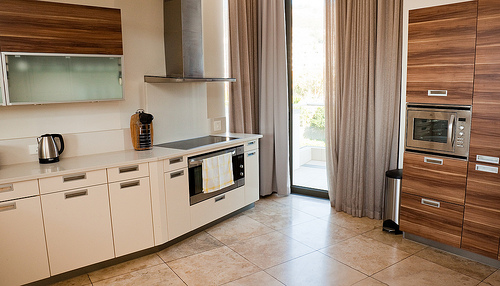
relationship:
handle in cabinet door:
[418, 199, 442, 210] [394, 182, 461, 247]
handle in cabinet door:
[479, 158, 498, 180] [465, 16, 497, 271]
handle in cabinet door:
[478, 154, 494, 169] [469, 108, 498, 228]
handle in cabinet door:
[63, 189, 88, 199] [49, 177, 123, 274]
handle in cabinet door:
[0, 203, 22, 207] [10, 188, 38, 281]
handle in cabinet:
[64, 169, 90, 185] [39, 182, 117, 278]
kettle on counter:
[34, 130, 68, 169] [1, 162, 180, 181]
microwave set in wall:
[404, 102, 471, 157] [388, 2, 498, 242]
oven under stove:
[189, 148, 258, 198] [154, 129, 238, 151]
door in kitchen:
[289, 0, 328, 197] [10, 7, 487, 277]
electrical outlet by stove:
[201, 115, 230, 139] [156, 140, 261, 217]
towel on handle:
[200, 152, 237, 194] [173, 149, 251, 178]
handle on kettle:
[46, 127, 73, 157] [39, 125, 77, 168]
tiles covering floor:
[177, 239, 307, 279] [258, 232, 309, 253]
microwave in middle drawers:
[397, 98, 480, 157] [401, 38, 458, 236]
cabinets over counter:
[7, 34, 115, 103] [16, 156, 123, 200]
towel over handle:
[195, 145, 264, 205] [188, 151, 257, 179]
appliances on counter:
[21, 124, 179, 164] [25, 163, 110, 173]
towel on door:
[200, 152, 237, 194] [185, 143, 244, 206]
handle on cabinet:
[476, 164, 499, 173] [462, 105, 497, 255]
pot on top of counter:
[34, 130, 65, 164] [1, 113, 265, 183]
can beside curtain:
[382, 169, 403, 236] [323, 0, 403, 219]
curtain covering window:
[226, 0, 403, 219] [284, 0, 328, 195]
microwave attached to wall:
[404, 102, 471, 157] [395, 0, 484, 257]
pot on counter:
[34, 130, 65, 164] [1, 113, 265, 183]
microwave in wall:
[404, 102, 471, 157] [395, 0, 484, 257]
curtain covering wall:
[327, 0, 405, 221] [201, 0, 471, 210]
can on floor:
[377, 166, 404, 235] [40, 190, 483, 283]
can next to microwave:
[377, 166, 404, 235] [404, 102, 471, 157]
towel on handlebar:
[200, 152, 237, 194] [188, 146, 237, 167]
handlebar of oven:
[188, 146, 237, 167] [185, 142, 246, 205]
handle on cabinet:
[63, 188, 90, 200] [39, 182, 117, 278]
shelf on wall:
[142, 74, 233, 84] [0, 0, 208, 141]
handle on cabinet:
[426, 87, 449, 97] [404, 1, 479, 106]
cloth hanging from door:
[200, 150, 237, 194] [184, 142, 245, 205]